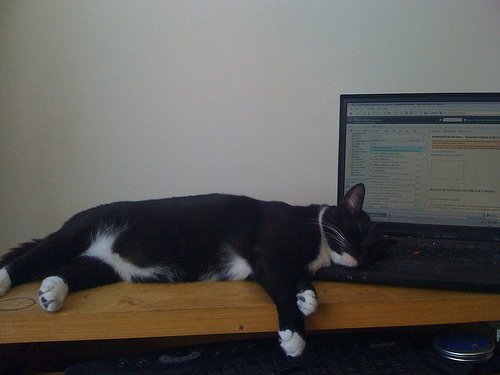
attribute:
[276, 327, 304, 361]
paw — white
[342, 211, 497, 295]
keyboard — black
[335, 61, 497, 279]
laptop — open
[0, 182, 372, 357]
cat — sleeping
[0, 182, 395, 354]
black/white cat — black, white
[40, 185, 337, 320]
cat — sleeping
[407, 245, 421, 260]
button — small, round, red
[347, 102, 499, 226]
screen — display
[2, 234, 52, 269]
tail — black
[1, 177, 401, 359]
cat — laying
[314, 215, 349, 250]
whiskers — white, curved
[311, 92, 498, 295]
laptop — black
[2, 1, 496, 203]
wall — smooth, colored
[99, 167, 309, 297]
cat — sleeping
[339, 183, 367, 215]
ear — black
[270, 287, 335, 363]
paws — white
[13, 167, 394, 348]
cat — resting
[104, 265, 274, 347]
desk — brown, wooden top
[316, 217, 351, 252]
whiskers — white